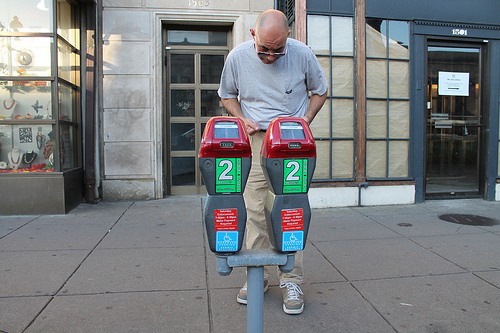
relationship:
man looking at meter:
[239, 24, 311, 101] [202, 118, 261, 241]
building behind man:
[82, 19, 167, 115] [239, 24, 311, 101]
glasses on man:
[257, 43, 285, 69] [239, 24, 311, 101]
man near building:
[239, 24, 311, 101] [82, 19, 167, 115]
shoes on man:
[287, 276, 309, 309] [239, 24, 311, 101]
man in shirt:
[239, 24, 311, 101] [265, 60, 330, 106]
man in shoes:
[239, 24, 311, 101] [287, 276, 309, 309]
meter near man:
[202, 118, 261, 241] [239, 24, 311, 101]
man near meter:
[239, 24, 311, 101] [202, 118, 261, 241]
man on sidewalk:
[239, 24, 311, 101] [101, 221, 167, 295]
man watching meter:
[239, 24, 311, 101] [202, 118, 261, 241]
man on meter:
[239, 24, 311, 101] [202, 118, 261, 241]